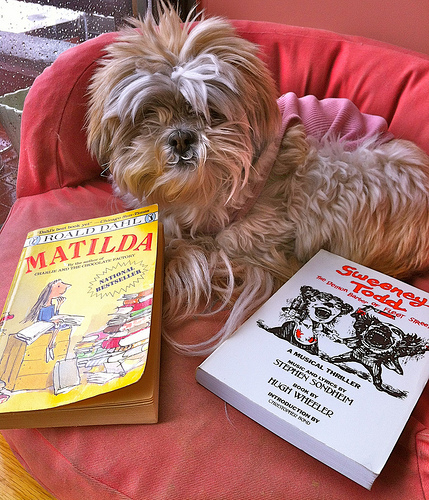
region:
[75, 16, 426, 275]
dog on cushion with books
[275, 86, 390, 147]
pink sweater on dog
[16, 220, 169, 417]
book on cushion with dog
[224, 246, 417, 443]
book on cushion with dog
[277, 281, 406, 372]
image on the book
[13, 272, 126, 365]
image on the book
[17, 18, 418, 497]
pink cushion with dog and books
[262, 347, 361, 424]
text on the book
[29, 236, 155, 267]
text on the book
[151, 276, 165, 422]
pages in the book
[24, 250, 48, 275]
The letter is red.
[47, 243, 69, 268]
The letter is red.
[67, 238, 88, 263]
The letter is red.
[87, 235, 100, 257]
The letter is red.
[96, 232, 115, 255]
The letter is red.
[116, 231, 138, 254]
The letter is red.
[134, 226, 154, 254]
The letter is red.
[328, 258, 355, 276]
The letter is red.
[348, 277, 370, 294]
The letter is red.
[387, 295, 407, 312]
The letter is red.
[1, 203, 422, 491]
Books sitting on pink pillow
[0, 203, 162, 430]
Old copy of child's book with yellow cover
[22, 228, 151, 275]
Red title of book on front cover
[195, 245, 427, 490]
Newer copy of book for adults with white cover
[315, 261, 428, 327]
Red title of book on front cover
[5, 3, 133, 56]
Raindrops clinging on back window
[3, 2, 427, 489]
Dog sitting next to two books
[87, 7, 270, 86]
Fur sticking up on the top of dog's head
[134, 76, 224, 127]
Fur hanging in dog's eyes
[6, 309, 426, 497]
Dirt on the front of pink pillow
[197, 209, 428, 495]
the book sweeney todd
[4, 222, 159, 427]
the book matilda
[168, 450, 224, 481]
red cushion on a chair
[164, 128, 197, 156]
brown nose on a dog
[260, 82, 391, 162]
pink cloth behind a dog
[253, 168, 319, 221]
tan fur on a dog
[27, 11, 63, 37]
water droplets on the window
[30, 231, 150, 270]
red writing on a book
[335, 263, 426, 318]
red writing on a book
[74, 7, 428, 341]
dog sitting in a chair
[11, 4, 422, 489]
dog on worn and dirty red pet bed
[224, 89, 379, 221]
folds on pink sweater around dog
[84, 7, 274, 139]
hair up and over sides of head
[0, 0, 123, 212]
water drops on window pane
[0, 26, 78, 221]
ledge and ceramic containers by window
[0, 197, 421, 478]
books with yellow and white covers in front of dog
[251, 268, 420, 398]
man and woman with large mouths holding hands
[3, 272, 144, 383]
girl sitting on case in front of book pile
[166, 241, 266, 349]
blonde and silky hair between books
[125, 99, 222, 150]
hidden eyes over dark nose